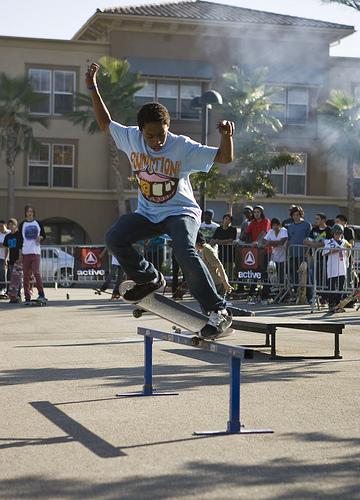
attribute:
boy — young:
[86, 60, 238, 342]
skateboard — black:
[120, 279, 233, 339]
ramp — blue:
[136, 327, 253, 433]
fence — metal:
[224, 240, 359, 306]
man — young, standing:
[21, 206, 48, 305]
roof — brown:
[99, 0, 356, 27]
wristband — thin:
[87, 87, 100, 90]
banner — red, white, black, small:
[73, 245, 109, 277]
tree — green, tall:
[1, 70, 48, 216]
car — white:
[40, 247, 75, 287]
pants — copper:
[18, 254, 48, 302]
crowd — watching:
[202, 203, 355, 299]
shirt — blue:
[110, 118, 218, 223]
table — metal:
[236, 311, 345, 357]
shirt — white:
[20, 221, 44, 256]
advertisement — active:
[70, 242, 113, 286]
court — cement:
[5, 306, 359, 495]